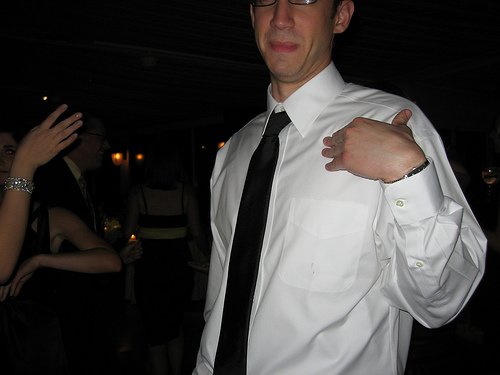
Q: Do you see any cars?
A: No, there are no cars.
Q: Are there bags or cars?
A: No, there are no cars or bags.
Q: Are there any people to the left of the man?
A: Yes, there is a person to the left of the man.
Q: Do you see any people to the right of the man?
A: No, the person is to the left of the man.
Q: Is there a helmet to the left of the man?
A: No, there is a person to the left of the man.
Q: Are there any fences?
A: No, there are no fences.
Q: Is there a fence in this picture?
A: No, there are no fences.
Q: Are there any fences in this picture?
A: No, there are no fences.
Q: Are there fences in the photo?
A: No, there are no fences.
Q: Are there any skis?
A: No, there are no skis.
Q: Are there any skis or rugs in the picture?
A: No, there are no skis or rugs.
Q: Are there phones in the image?
A: No, there are no phones.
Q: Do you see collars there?
A: Yes, there is a collar.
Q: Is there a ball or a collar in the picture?
A: Yes, there is a collar.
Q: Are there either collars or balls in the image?
A: Yes, there is a collar.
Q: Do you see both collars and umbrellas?
A: No, there is a collar but no umbrellas.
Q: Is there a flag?
A: No, there are no flags.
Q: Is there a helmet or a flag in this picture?
A: No, there are no flags or helmets.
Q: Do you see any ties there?
A: Yes, there is a tie.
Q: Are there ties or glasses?
A: Yes, there is a tie.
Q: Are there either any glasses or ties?
A: Yes, there is a tie.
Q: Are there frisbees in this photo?
A: No, there are no frisbees.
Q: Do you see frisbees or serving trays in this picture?
A: No, there are no frisbees or serving trays.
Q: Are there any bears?
A: No, there are no bears.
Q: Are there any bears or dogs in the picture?
A: No, there are no bears or dogs.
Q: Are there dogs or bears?
A: No, there are no bears or dogs.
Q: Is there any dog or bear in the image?
A: No, there are no bears or dogs.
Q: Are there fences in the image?
A: No, there are no fences.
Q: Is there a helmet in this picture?
A: No, there are no helmets.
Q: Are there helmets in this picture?
A: No, there are no helmets.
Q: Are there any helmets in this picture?
A: No, there are no helmets.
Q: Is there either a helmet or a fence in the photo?
A: No, there are no helmets or fences.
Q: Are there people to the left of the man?
A: Yes, there is a person to the left of the man.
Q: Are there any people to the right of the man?
A: No, the person is to the left of the man.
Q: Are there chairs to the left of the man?
A: No, there is a person to the left of the man.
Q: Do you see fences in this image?
A: No, there are no fences.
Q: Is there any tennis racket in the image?
A: No, there are no rackets.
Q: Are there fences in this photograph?
A: No, there are no fences.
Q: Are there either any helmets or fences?
A: No, there are no fences or helmets.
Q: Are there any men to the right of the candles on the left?
A: Yes, there is a man to the right of the candles.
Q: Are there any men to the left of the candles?
A: No, the man is to the right of the candles.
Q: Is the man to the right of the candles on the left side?
A: Yes, the man is to the right of the candles.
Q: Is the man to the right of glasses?
A: No, the man is to the right of the candles.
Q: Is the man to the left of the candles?
A: No, the man is to the right of the candles.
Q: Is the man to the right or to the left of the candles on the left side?
A: The man is to the right of the candles.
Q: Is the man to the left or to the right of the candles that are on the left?
A: The man is to the right of the candles.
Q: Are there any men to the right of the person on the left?
A: Yes, there is a man to the right of the person.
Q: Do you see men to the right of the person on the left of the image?
A: Yes, there is a man to the right of the person.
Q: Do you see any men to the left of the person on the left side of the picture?
A: No, the man is to the right of the person.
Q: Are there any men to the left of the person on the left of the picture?
A: No, the man is to the right of the person.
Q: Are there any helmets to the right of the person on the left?
A: No, there is a man to the right of the person.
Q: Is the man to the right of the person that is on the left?
A: Yes, the man is to the right of the person.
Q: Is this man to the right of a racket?
A: No, the man is to the right of the person.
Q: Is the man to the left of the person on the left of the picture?
A: No, the man is to the right of the person.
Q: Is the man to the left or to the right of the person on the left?
A: The man is to the right of the person.